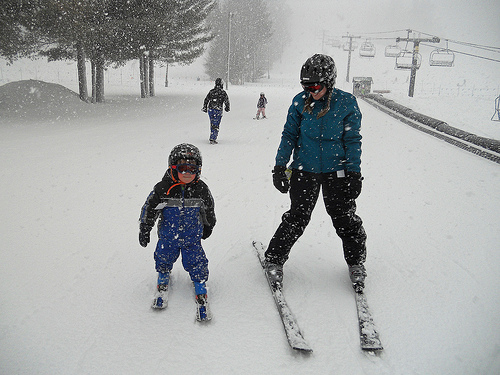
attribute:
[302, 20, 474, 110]
ski lift — moving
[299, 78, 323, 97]
ski goggles — pictured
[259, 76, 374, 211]
jacket — teal 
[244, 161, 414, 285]
pants — black 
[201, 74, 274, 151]
people — playing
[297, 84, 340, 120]
hair — long, blonde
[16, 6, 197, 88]
tree — green, tall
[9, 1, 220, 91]
tree — tall, green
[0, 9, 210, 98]
tree — green, tall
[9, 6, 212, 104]
tree — tall, green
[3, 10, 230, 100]
tree — green, tall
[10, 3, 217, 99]
tree — tall, green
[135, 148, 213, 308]
person — little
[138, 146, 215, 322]
person — LITTLE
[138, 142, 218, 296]
boy — LITTLE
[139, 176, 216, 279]
suite — BLUE AND BLACK, SNOW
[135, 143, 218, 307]
boys — LITTLE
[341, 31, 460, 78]
lift — SKI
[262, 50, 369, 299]
lady — SNOW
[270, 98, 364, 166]
jacket — GREEN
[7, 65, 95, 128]
snow — drifts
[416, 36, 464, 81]
ski car — empty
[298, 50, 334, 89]
helmet — black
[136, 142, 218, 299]
child — little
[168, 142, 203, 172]
helmet — black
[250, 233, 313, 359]
ski — snow covered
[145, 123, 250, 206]
ski helmet — black